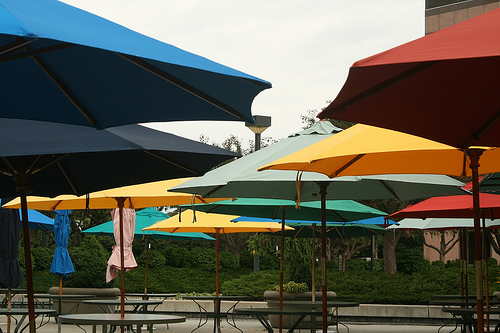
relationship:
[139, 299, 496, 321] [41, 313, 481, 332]
wall around patio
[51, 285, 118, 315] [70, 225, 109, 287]
cement planter with bush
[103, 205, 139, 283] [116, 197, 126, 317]
umbrella on pole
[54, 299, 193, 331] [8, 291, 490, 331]
table on patio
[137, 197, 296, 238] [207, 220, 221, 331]
umbrella on pole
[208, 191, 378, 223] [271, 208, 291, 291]
umbrella on pole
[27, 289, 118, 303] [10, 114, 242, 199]
table under umbrella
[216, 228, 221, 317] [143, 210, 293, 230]
pole under umbrella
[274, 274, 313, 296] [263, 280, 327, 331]
bushes in pot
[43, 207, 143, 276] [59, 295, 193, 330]
umbrellas on tables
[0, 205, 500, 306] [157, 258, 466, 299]
bushes by wall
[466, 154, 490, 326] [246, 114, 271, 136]
pole on light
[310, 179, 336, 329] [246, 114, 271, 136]
pole on light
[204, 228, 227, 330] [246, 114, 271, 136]
pole on light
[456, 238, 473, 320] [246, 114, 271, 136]
pole on light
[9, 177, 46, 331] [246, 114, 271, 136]
pole on light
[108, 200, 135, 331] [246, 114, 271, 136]
pole on light